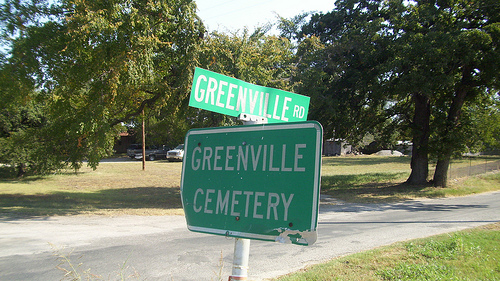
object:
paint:
[270, 225, 317, 246]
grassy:
[275, 215, 500, 281]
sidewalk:
[0, 188, 500, 280]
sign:
[179, 119, 322, 245]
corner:
[176, 189, 202, 230]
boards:
[179, 65, 323, 248]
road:
[0, 187, 499, 280]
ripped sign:
[253, 212, 322, 247]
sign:
[187, 65, 312, 124]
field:
[0, 0, 499, 281]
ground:
[451, 180, 491, 219]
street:
[0, 191, 497, 281]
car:
[134, 147, 170, 161]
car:
[167, 143, 185, 162]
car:
[126, 143, 149, 159]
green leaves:
[0, 0, 202, 180]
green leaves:
[188, 11, 328, 127]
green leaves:
[308, 1, 498, 154]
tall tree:
[293, 0, 499, 191]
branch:
[369, 91, 414, 121]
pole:
[140, 108, 151, 172]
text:
[178, 67, 328, 247]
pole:
[230, 237, 252, 281]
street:
[84, 156, 410, 170]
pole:
[238, 120, 258, 129]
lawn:
[0, 161, 185, 227]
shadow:
[306, 163, 490, 213]